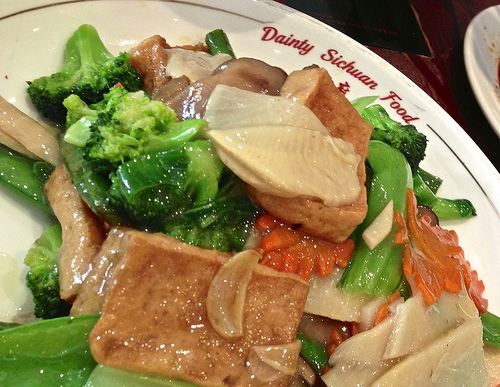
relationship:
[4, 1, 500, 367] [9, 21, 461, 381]
dish filled with meat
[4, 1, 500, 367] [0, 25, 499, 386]
dish filled with food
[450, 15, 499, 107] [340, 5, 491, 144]
plate sitting on table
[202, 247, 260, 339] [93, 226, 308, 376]
garlic on meat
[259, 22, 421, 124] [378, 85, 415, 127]
letters says food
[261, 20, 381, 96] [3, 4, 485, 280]
dainty sichuan written on plate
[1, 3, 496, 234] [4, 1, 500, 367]
stripe on dish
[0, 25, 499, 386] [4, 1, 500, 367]
food on dish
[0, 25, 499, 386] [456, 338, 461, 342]
food mingled with food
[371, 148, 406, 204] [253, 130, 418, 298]
green bean mingling with food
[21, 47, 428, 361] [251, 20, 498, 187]
food on plate